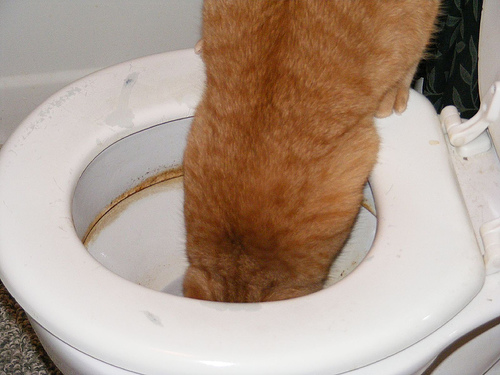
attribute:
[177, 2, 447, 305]
cat — tan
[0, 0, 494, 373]
toilet — white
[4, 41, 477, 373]
seat — down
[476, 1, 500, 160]
lid — up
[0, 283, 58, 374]
rug — gray, blue